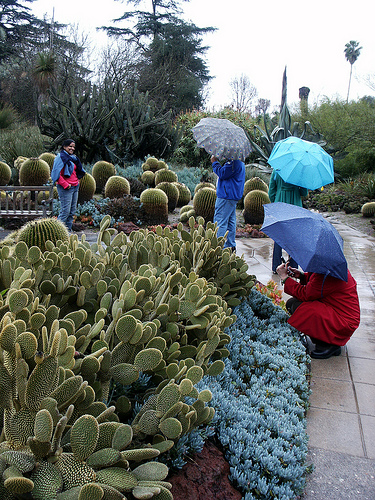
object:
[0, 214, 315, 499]
garden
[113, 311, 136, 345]
cacti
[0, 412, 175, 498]
plants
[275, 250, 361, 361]
woman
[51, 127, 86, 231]
people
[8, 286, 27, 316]
cactus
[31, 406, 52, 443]
cactus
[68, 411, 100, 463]
cacti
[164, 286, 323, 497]
succulent